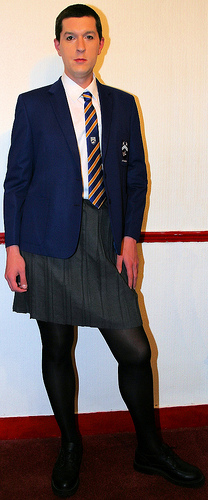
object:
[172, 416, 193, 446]
carpet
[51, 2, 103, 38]
hair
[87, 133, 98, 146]
logo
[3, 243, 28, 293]
right hand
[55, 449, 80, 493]
shoe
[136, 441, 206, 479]
shoe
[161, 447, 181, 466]
lace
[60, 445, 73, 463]
lace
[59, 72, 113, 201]
shirt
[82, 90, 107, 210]
tie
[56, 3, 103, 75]
head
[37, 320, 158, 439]
stockings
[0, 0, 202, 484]
man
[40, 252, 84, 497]
legs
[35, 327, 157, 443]
nylons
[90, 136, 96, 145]
emblem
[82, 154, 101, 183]
stripes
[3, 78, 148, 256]
jacket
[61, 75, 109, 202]
white shirt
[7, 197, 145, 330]
skirt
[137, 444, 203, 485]
black shoe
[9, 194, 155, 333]
pleated skirt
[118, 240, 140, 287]
hand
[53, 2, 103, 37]
short hair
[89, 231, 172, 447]
leg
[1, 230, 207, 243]
wood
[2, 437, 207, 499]
floor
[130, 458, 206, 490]
sole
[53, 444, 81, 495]
sole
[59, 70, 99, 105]
collar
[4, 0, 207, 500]
person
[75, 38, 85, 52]
nose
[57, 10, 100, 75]
face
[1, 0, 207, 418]
wall